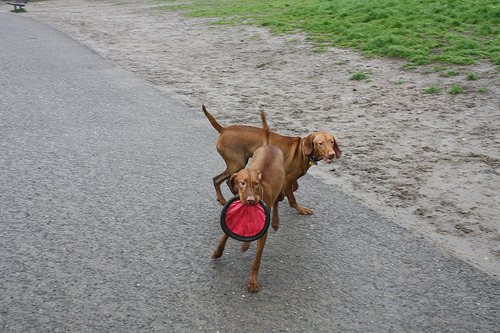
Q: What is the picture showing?
A: It is showing a road.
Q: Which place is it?
A: It is a road.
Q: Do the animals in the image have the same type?
A: Yes, all the animals are dogs.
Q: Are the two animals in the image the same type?
A: Yes, all the animals are dogs.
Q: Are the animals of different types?
A: No, all the animals are dogs.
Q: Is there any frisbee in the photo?
A: Yes, there is a frisbee.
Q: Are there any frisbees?
A: Yes, there is a frisbee.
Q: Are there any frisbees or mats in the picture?
A: Yes, there is a frisbee.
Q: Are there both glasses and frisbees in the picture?
A: No, there is a frisbee but no glasses.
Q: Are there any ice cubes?
A: No, there are no ice cubes.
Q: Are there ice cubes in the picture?
A: No, there are no ice cubes.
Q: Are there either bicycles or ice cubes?
A: No, there are no ice cubes or bicycles.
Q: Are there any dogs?
A: Yes, there is a dog.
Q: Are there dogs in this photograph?
A: Yes, there is a dog.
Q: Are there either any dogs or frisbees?
A: Yes, there is a dog.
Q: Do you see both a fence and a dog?
A: No, there is a dog but no fences.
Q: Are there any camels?
A: No, there are no camels.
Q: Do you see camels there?
A: No, there are no camels.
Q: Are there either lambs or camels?
A: No, there are no camels or lambs.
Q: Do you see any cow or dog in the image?
A: Yes, there is a dog.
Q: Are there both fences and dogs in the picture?
A: No, there is a dog but no fences.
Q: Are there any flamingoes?
A: No, there are no flamingoes.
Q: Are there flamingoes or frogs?
A: No, there are no flamingoes or frogs.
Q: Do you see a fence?
A: No, there are no fences.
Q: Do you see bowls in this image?
A: No, there are no bowls.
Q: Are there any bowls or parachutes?
A: No, there are no bowls or parachutes.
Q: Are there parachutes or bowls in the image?
A: No, there are no bowls or parachutes.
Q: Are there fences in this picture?
A: No, there are no fences.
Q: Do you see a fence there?
A: No, there are no fences.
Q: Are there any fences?
A: No, there are no fences.